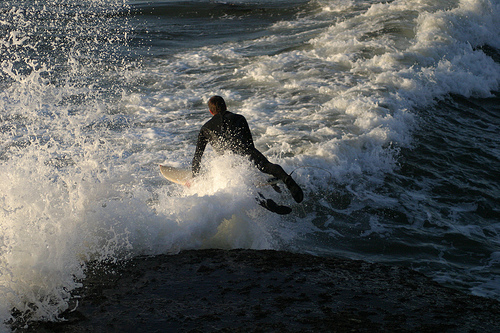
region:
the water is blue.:
[4, 5, 495, 332]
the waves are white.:
[7, 2, 490, 304]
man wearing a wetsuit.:
[180, 102, 310, 221]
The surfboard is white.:
[147, 155, 220, 187]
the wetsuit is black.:
[187, 107, 303, 209]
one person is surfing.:
[145, 82, 330, 236]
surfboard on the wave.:
[147, 83, 311, 224]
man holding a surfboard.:
[155, 153, 312, 218]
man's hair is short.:
[198, 90, 230, 116]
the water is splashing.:
[2, 5, 155, 202]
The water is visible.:
[295, 25, 399, 175]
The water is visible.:
[335, 78, 409, 258]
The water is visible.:
[415, 115, 479, 260]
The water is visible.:
[430, 20, 491, 182]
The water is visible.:
[332, 92, 492, 282]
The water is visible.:
[384, 152, 494, 254]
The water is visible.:
[372, 158, 427, 278]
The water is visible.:
[391, 172, 478, 326]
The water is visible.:
[392, 132, 449, 219]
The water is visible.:
[397, 51, 498, 256]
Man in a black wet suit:
[156, 74, 327, 222]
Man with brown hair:
[200, 91, 243, 123]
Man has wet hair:
[198, 86, 233, 119]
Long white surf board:
[161, 154, 236, 201]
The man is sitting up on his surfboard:
[169, 86, 304, 203]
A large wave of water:
[71, 37, 484, 287]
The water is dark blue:
[128, 15, 267, 59]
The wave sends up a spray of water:
[23, 20, 243, 273]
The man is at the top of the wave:
[135, 82, 329, 231]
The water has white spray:
[13, 12, 420, 267]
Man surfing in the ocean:
[144, 84, 321, 234]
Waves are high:
[3, 8, 170, 318]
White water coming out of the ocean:
[8, 158, 191, 306]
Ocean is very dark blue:
[215, 258, 385, 330]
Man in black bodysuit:
[191, 95, 295, 211]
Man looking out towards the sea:
[148, 84, 317, 238]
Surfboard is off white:
[153, 152, 297, 216]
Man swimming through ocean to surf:
[148, 91, 305, 226]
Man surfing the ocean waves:
[155, 73, 335, 231]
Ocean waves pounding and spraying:
[2, 10, 154, 330]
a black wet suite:
[216, 107, 266, 202]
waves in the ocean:
[333, 100, 440, 177]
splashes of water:
[53, 83, 120, 153]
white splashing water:
[18, 234, 58, 287]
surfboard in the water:
[156, 160, 187, 182]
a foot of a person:
[256, 192, 298, 215]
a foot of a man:
[280, 170, 308, 202]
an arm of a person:
[185, 132, 208, 169]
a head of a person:
[205, 90, 226, 115]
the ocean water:
[201, 279, 276, 321]